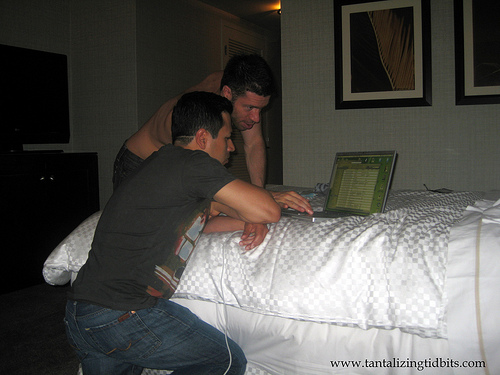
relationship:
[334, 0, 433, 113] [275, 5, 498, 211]
art hanging on wall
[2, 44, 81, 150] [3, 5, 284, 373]
television in background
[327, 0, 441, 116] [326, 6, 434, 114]
art in frame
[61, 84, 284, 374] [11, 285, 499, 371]
man on floor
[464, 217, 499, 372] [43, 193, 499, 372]
trim on sheets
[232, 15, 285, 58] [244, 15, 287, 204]
top of door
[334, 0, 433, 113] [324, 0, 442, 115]
art in frame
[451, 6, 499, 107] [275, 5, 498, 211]
picture on wall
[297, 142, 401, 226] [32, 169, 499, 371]
computer on bed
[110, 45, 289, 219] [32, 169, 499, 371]
man over bed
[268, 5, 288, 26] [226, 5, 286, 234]
light in hall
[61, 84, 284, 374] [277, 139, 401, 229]
man looking at laptop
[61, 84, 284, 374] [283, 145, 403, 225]
man viewing laptop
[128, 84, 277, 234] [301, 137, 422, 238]
man interested with a laptop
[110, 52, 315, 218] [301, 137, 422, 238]
man interested with a laptop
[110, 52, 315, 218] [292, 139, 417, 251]
man looking at a laptop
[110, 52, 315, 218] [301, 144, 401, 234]
man busy with laptop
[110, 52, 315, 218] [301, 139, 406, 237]
man interested in a laptop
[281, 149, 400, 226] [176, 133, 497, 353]
computer on a bed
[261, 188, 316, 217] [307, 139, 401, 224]
hand working a laptop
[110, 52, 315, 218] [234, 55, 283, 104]
man with hair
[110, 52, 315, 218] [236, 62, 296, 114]
man with hair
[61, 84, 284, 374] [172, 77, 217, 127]
man with hair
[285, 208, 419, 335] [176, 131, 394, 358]
comforter on bed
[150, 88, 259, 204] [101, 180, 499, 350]
guy leaning on bed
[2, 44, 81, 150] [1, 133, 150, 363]
television on dresser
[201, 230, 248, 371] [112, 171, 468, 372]
power cord hanging off bed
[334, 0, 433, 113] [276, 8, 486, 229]
art on wall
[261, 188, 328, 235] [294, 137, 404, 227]
hand on laptop